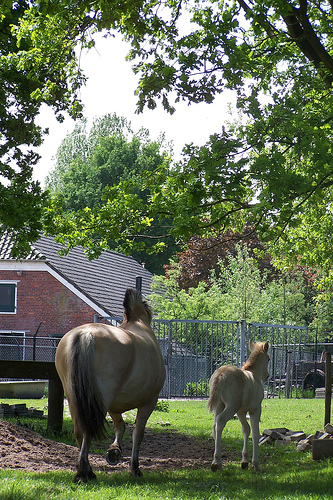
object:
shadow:
[84, 466, 332, 498]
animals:
[54, 288, 167, 488]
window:
[0, 281, 16, 316]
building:
[0, 221, 171, 397]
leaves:
[290, 114, 319, 160]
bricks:
[0, 271, 114, 335]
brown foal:
[205, 338, 270, 473]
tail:
[65, 331, 115, 444]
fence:
[92, 311, 332, 399]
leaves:
[143, 64, 184, 100]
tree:
[0, 0, 332, 401]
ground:
[0, 390, 332, 499]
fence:
[0, 335, 60, 364]